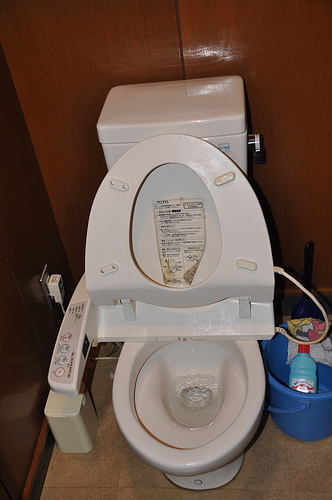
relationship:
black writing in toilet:
[68, 303, 84, 321] [75, 75, 279, 483]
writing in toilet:
[65, 298, 84, 317] [42, 75, 284, 490]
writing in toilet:
[152, 200, 204, 233] [83, 100, 281, 497]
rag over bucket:
[286, 316, 331, 363] [277, 386, 329, 440]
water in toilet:
[170, 371, 224, 427] [105, 156, 249, 471]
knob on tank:
[250, 128, 268, 158] [88, 75, 271, 184]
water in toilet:
[170, 371, 224, 427] [75, 75, 279, 483]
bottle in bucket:
[287, 341, 318, 393] [260, 315, 330, 444]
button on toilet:
[192, 478, 204, 486] [75, 75, 279, 483]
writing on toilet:
[67, 299, 85, 318] [75, 75, 279, 483]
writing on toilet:
[158, 195, 202, 276] [81, 88, 288, 468]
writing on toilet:
[150, 198, 205, 281] [87, 148, 267, 406]